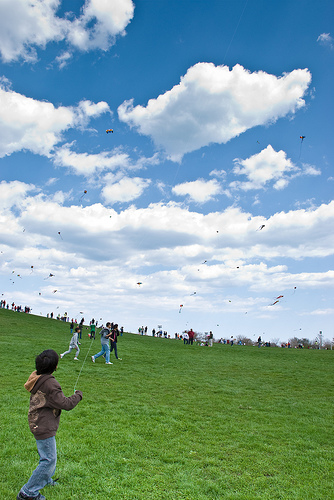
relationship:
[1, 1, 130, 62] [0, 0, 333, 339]
cloud in formation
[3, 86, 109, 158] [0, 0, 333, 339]
cloud in formation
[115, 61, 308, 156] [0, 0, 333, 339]
cloud in formation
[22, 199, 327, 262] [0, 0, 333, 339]
cloud in formation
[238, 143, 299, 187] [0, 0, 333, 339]
cloud in formation